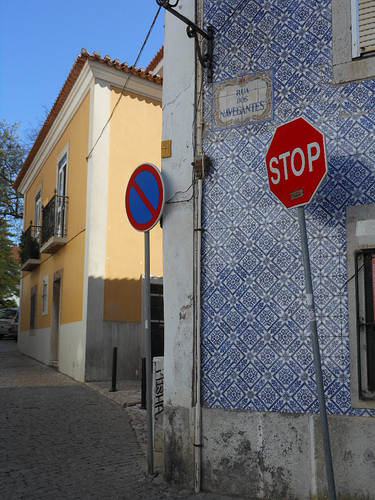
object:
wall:
[92, 86, 162, 277]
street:
[0, 348, 158, 499]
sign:
[264, 115, 329, 211]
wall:
[192, 6, 375, 413]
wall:
[161, 1, 196, 436]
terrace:
[40, 193, 69, 254]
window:
[57, 154, 66, 233]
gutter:
[12, 48, 92, 196]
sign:
[213, 77, 274, 122]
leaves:
[1, 132, 13, 209]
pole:
[291, 206, 336, 498]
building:
[160, 3, 375, 500]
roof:
[144, 46, 164, 77]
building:
[13, 42, 162, 384]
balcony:
[38, 194, 69, 255]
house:
[12, 47, 162, 383]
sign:
[123, 162, 165, 232]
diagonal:
[132, 180, 155, 215]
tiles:
[194, 6, 375, 418]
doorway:
[51, 269, 62, 370]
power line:
[85, 1, 165, 161]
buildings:
[12, 0, 371, 500]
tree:
[0, 114, 14, 308]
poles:
[109, 345, 146, 406]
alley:
[87, 278, 166, 393]